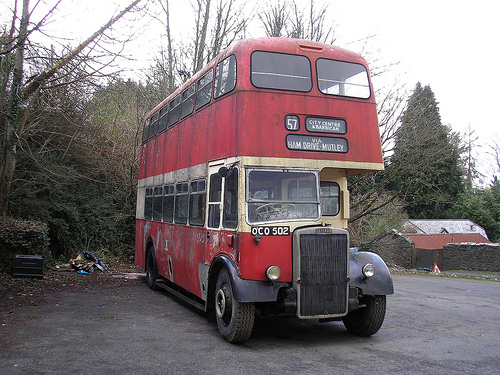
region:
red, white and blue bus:
[135, 38, 394, 345]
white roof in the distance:
[401, 220, 491, 241]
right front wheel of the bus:
[205, 256, 259, 341]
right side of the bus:
[132, 33, 256, 343]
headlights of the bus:
[265, 260, 377, 280]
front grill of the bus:
[293, 228, 350, 319]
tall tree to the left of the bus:
[387, 80, 458, 218]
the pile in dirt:
[72, 249, 129, 290]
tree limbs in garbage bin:
[7, 210, 54, 287]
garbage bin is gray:
[7, 217, 57, 279]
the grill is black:
[299, 226, 343, 324]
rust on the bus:
[152, 225, 226, 268]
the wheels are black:
[215, 286, 385, 341]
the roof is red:
[417, 226, 490, 241]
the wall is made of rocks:
[441, 240, 496, 267]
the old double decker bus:
[133, 37, 395, 342]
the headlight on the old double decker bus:
[266, 264, 280, 281]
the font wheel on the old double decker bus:
[211, 265, 256, 343]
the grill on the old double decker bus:
[295, 221, 350, 319]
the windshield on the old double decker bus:
[245, 170, 321, 223]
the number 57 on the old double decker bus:
[285, 116, 298, 128]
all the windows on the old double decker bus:
[140, 50, 370, 230]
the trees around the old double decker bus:
[0, 0, 498, 275]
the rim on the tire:
[215, 281, 229, 330]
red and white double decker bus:
[121, 36, 415, 348]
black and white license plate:
[246, 224, 286, 239]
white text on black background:
[280, 109, 352, 158]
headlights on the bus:
[263, 263, 378, 287]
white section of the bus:
[131, 167, 349, 230]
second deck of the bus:
[124, 37, 380, 169]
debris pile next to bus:
[61, 249, 108, 275]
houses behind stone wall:
[398, 215, 489, 265]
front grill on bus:
[294, 237, 345, 312]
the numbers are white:
[289, 117, 296, 129]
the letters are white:
[289, 136, 342, 155]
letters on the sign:
[294, 138, 353, 154]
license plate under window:
[241, 177, 316, 230]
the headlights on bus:
[260, 257, 384, 284]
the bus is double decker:
[148, 74, 380, 333]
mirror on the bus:
[217, 162, 232, 179]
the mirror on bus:
[215, 162, 235, 183]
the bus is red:
[143, 47, 335, 272]